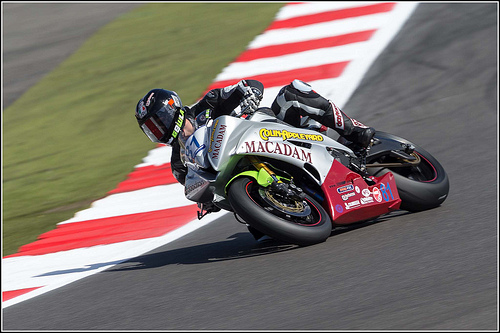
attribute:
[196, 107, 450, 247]
motorcycle — red, silver, black, gray, maroon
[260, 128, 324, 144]
word — yellow, red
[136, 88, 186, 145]
helmet — black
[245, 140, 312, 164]
word — red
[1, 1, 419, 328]
stripes — red, white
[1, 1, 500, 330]
track — gray, pavement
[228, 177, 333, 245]
tire — smooth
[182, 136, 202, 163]
number — blue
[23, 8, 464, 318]
scene — outdoor